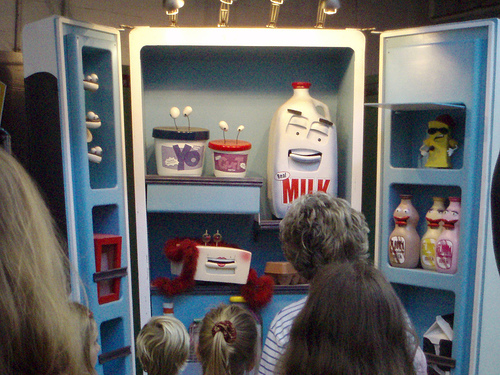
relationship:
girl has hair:
[193, 301, 260, 373] [196, 301, 260, 374]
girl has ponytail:
[193, 301, 260, 373] [201, 331, 235, 374]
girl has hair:
[273, 260, 421, 374] [274, 259, 417, 374]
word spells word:
[171, 142, 202, 175] [171, 142, 202, 175]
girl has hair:
[273, 192, 420, 374] [277, 185, 372, 283]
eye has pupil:
[285, 113, 312, 141] [294, 130, 301, 136]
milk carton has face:
[263, 79, 340, 221] [282, 105, 335, 174]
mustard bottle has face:
[416, 113, 459, 166] [426, 125, 450, 147]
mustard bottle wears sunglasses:
[416, 113, 459, 166] [428, 125, 451, 137]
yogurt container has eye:
[154, 104, 210, 179] [183, 104, 194, 131]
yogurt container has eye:
[154, 104, 210, 179] [167, 104, 181, 132]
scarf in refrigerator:
[150, 235, 277, 312] [19, 17, 500, 374]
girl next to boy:
[193, 301, 260, 373] [129, 315, 196, 374]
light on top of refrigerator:
[313, 0, 340, 31] [19, 17, 500, 374]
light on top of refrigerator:
[268, 0, 286, 28] [19, 17, 500, 374]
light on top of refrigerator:
[217, 0, 237, 29] [19, 17, 500, 374]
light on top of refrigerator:
[158, 0, 188, 27] [19, 17, 500, 374]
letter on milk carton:
[282, 176, 300, 207] [263, 79, 340, 221]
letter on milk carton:
[300, 176, 309, 202] [263, 79, 340, 221]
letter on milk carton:
[308, 179, 314, 199] [263, 79, 340, 221]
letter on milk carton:
[315, 178, 333, 197] [263, 79, 340, 221]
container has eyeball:
[207, 137, 254, 181] [218, 118, 230, 143]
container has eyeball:
[207, 137, 254, 181] [234, 123, 248, 144]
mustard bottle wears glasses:
[416, 113, 459, 166] [428, 125, 451, 137]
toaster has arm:
[170, 241, 253, 289] [156, 237, 202, 297]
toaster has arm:
[170, 241, 253, 289] [242, 268, 276, 306]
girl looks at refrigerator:
[273, 192, 420, 374] [19, 17, 500, 374]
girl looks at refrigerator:
[193, 301, 260, 373] [19, 17, 500, 374]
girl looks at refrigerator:
[273, 260, 421, 374] [19, 17, 500, 374]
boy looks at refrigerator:
[129, 315, 196, 374] [19, 17, 500, 374]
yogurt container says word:
[154, 104, 210, 179] [171, 142, 202, 175]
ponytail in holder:
[201, 331, 235, 374] [211, 319, 238, 345]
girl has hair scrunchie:
[193, 301, 260, 373] [211, 317, 239, 347]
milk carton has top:
[263, 79, 340, 221] [290, 80, 314, 90]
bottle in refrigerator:
[386, 190, 422, 271] [19, 17, 500, 374]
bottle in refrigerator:
[434, 191, 461, 274] [19, 17, 500, 374]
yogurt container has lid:
[154, 104, 210, 179] [151, 126, 213, 144]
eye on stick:
[183, 104, 194, 131] [186, 115, 193, 134]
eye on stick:
[167, 104, 181, 132] [173, 117, 182, 133]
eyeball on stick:
[218, 118, 230, 143] [222, 129, 228, 146]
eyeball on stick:
[234, 123, 248, 144] [235, 130, 242, 146]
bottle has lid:
[422, 190, 449, 274] [430, 192, 447, 204]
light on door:
[398, 27, 459, 82] [373, 19, 500, 373]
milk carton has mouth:
[263, 79, 340, 221] [288, 148, 322, 164]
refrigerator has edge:
[19, 17, 500, 374] [124, 23, 368, 339]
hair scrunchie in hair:
[211, 317, 239, 347] [196, 301, 260, 374]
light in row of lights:
[158, 0, 188, 27] [158, 0, 342, 30]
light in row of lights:
[217, 0, 237, 29] [158, 0, 342, 30]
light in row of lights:
[268, 0, 286, 28] [158, 0, 342, 30]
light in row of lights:
[313, 0, 340, 31] [158, 0, 342, 30]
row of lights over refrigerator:
[158, 0, 342, 30] [19, 17, 500, 374]